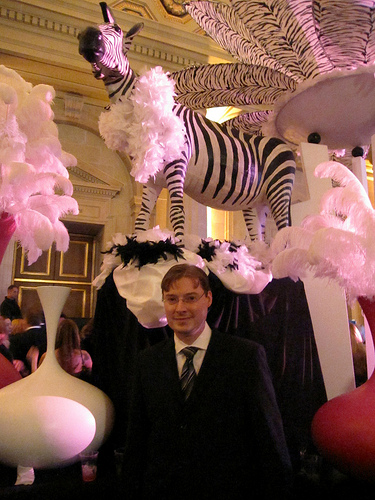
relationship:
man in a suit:
[126, 263, 301, 500] [148, 356, 159, 386]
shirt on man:
[168, 325, 231, 382] [126, 263, 301, 500]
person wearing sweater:
[0, 284, 23, 320] [0, 297, 26, 335]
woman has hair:
[53, 319, 97, 378] [144, 260, 221, 301]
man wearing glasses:
[126, 263, 301, 500] [162, 291, 207, 305]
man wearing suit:
[120, 254, 298, 492] [119, 325, 286, 494]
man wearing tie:
[126, 263, 301, 500] [178, 345, 197, 406]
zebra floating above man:
[76, 1, 296, 246] [126, 263, 301, 500]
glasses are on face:
[162, 291, 208, 301] [161, 277, 207, 332]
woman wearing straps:
[27, 319, 93, 380] [70, 336, 94, 363]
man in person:
[126, 263, 301, 500] [0, 284, 23, 320]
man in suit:
[126, 263, 301, 500] [123, 336, 290, 498]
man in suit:
[126, 263, 301, 500] [86, 252, 290, 498]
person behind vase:
[1, 282, 25, 319] [0, 273, 125, 489]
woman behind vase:
[27, 319, 93, 380] [0, 273, 125, 489]